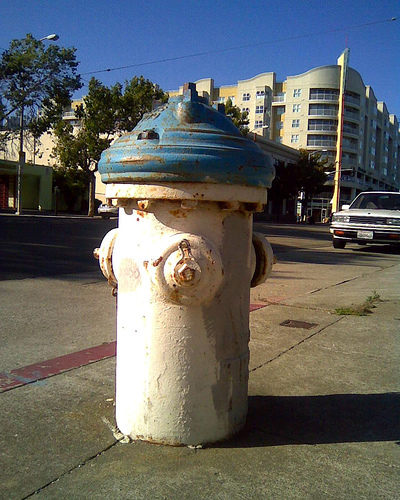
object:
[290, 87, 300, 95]
window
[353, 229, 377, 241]
plate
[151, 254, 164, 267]
spots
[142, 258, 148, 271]
spots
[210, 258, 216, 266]
spots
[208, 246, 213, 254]
spots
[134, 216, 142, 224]
spots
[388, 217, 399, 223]
headlight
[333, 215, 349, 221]
headlight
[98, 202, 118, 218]
car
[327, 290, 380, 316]
grass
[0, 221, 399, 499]
concrete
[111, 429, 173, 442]
paint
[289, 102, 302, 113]
window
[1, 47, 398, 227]
building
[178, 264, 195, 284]
lug nut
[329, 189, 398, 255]
car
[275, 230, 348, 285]
road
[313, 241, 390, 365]
plants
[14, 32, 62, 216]
lamp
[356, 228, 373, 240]
license plate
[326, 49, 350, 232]
curbing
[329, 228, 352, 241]
headlight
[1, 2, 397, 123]
sky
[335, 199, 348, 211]
mirror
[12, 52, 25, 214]
pole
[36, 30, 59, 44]
light fixture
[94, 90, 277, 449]
body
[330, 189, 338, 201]
pillar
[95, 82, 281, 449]
fire hydrant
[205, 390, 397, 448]
shadow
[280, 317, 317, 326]
cover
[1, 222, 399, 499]
path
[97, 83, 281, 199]
top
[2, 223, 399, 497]
sidewalk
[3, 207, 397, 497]
ground